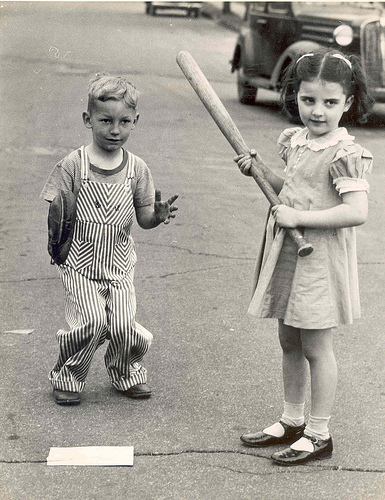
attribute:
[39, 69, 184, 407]
boy — crouching, little, striped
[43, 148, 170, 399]
overalls — striped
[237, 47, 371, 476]
girl — little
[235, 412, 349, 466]
shoes — black, shiny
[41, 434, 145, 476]
paper — blank, white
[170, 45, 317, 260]
bat — wooden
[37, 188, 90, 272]
mitt — leather, old fashioned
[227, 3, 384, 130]
truck — old fashioned, old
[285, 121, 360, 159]
collar — lace, white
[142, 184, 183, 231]
hand — dirty, extended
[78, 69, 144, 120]
hair — blonde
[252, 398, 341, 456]
socks — white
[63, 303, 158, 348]
knees — bent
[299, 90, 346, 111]
eyes — dark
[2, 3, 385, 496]
street — cracked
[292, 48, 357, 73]
barrettes — pinned